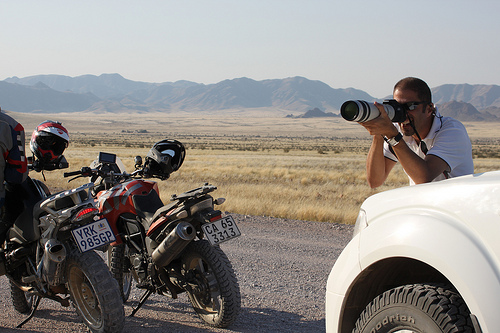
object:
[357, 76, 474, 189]
man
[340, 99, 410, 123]
camera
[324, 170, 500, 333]
car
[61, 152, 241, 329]
motorcycle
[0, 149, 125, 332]
motorcycle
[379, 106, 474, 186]
shirt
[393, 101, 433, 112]
glasses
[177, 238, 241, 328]
tire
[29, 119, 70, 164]
helmet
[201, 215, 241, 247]
license plate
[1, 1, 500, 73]
clouds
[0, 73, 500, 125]
mountains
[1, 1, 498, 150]
background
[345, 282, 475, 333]
wheel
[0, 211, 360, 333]
gravel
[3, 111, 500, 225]
grass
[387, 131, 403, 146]
watch